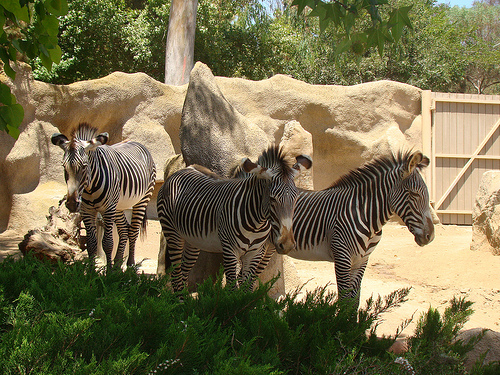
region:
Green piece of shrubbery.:
[403, 300, 468, 363]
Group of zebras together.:
[8, 121, 447, 328]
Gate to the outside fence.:
[425, 104, 498, 215]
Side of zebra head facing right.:
[376, 143, 443, 250]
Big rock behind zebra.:
[179, 61, 253, 165]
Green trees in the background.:
[36, 20, 143, 65]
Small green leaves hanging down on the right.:
[6, 1, 66, 71]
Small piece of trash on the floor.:
[374, 325, 414, 365]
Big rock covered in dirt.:
[474, 163, 489, 259]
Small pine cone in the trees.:
[156, 351, 202, 372]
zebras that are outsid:
[19, 58, 484, 318]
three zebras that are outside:
[11, 68, 492, 355]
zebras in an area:
[11, 44, 489, 371]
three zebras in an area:
[37, 41, 482, 312]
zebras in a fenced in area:
[8, 1, 493, 352]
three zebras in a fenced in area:
[33, 4, 400, 374]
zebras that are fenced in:
[27, 5, 477, 371]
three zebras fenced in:
[19, 45, 496, 321]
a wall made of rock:
[23, 26, 478, 311]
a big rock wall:
[9, 5, 499, 294]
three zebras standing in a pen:
[49, 103, 437, 320]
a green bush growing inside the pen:
[2, 308, 432, 373]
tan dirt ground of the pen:
[424, 255, 493, 295]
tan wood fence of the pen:
[439, 113, 469, 184]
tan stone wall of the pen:
[172, 76, 352, 141]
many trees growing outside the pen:
[225, 15, 387, 66]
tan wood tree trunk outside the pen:
[163, 2, 208, 89]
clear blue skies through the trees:
[241, 0, 290, 29]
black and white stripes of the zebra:
[171, 176, 229, 223]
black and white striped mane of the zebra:
[63, 120, 103, 141]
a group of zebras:
[32, 115, 439, 312]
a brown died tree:
[168, 2, 195, 84]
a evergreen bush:
[5, 270, 455, 367]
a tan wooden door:
[433, 88, 499, 229]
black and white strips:
[158, 150, 295, 287]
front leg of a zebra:
[336, 271, 368, 305]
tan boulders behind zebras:
[188, 75, 408, 151]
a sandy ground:
[386, 252, 491, 332]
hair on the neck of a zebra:
[343, 158, 399, 190]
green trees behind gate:
[229, 8, 479, 74]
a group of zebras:
[45, 124, 440, 293]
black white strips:
[183, 183, 274, 230]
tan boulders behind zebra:
[156, 73, 334, 147]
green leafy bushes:
[0, 251, 401, 371]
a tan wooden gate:
[436, 97, 497, 220]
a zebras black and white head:
[50, 127, 110, 218]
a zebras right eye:
[261, 190, 278, 205]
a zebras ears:
[400, 150, 430, 175]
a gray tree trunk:
[162, 1, 192, 79]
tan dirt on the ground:
[384, 238, 482, 324]